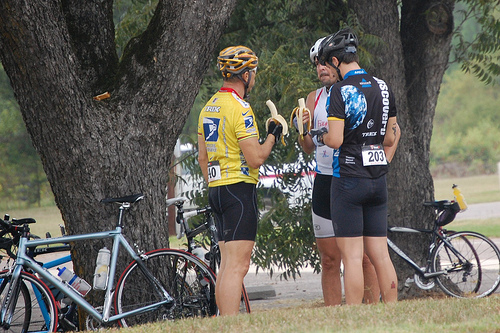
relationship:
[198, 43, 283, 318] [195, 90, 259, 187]
man wearing shirt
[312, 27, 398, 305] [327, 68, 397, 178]
man wearing black shirt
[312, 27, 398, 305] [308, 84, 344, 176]
man wearing shirt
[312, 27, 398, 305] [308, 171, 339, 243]
man wearing shorts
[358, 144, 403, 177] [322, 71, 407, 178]
sticker 203 on shirt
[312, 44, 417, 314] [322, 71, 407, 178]
man wearing shirt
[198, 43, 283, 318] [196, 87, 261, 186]
man in yellow shirt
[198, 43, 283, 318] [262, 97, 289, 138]
man eating banana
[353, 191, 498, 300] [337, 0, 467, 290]
bike resting against tree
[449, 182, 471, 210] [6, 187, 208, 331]
bottle on bike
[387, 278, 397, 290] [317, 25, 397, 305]
tatoo on man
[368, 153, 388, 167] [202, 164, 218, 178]
number on sticker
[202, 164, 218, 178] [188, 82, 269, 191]
sticker of shirt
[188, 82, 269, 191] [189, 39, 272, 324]
shirt of man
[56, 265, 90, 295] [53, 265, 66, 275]
bottle with top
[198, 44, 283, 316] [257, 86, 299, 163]
man eating banana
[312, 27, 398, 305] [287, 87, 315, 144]
man eating banana